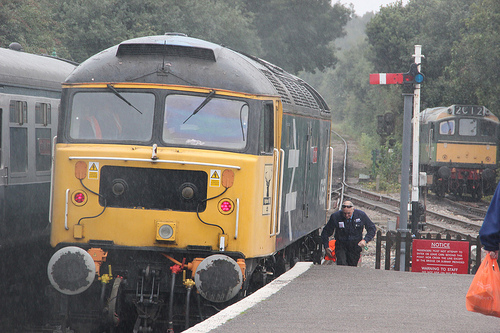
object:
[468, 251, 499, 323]
structure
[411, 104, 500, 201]
train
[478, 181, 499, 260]
person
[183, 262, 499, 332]
platform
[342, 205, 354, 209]
sunglasses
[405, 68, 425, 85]
signal lights.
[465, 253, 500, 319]
bag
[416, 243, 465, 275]
lettering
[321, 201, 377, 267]
man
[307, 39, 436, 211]
area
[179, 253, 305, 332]
edge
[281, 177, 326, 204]
wall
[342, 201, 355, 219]
head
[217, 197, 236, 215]
led light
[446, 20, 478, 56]
green leaves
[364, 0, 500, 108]
tree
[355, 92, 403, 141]
bush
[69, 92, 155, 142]
window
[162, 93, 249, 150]
window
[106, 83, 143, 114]
windshiel wiper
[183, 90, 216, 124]
windshiel wiper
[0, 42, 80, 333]
train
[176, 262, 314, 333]
line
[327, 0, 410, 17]
cloudy sky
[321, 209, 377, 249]
jacket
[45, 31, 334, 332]
train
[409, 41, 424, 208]
post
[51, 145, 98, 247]
edge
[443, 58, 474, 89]
part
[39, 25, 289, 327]
front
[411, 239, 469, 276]
notice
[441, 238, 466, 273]
part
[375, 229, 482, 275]
fence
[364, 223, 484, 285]
fence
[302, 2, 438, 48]
sky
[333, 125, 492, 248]
tracks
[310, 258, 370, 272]
stairs